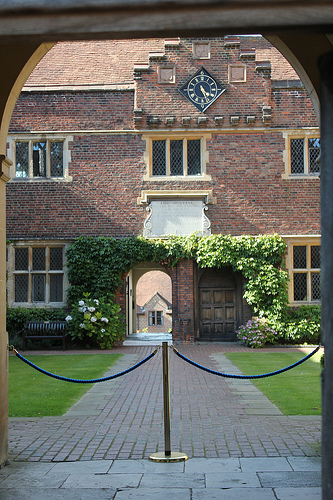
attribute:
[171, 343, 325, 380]
rope — blue, separation barrier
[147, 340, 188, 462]
post — gold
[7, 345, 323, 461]
sidewalk — brick, off red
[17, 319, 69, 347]
bench — black, comfortable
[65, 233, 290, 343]
foliage — green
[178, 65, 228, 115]
clock — diamond, high, square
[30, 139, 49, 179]
window pane — open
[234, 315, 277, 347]
bush — small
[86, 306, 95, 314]
flower — white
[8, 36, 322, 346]
wall — brick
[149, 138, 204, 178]
window — square, paneled, framed, large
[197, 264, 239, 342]
door — closed, old, wooden, brown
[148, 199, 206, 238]
plaque — describing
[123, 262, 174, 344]
walkway — open, opened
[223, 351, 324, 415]
grass — green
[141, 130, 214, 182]
frame — yellow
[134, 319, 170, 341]
path — foot